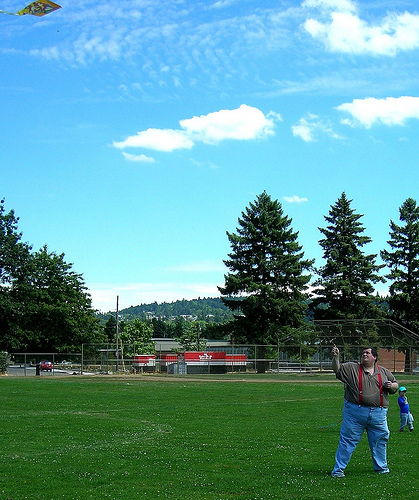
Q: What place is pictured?
A: It is a park.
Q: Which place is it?
A: It is a park.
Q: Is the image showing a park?
A: Yes, it is showing a park.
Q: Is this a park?
A: Yes, it is a park.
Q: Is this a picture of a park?
A: Yes, it is showing a park.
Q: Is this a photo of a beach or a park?
A: It is showing a park.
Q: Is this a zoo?
A: No, it is a park.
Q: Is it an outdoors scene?
A: Yes, it is outdoors.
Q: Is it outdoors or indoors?
A: It is outdoors.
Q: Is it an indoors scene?
A: No, it is outdoors.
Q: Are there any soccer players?
A: No, there are no soccer players.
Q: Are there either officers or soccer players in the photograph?
A: No, there are no soccer players or officers.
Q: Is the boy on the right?
A: Yes, the boy is on the right of the image.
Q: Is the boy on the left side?
A: No, the boy is on the right of the image.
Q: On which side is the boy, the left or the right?
A: The boy is on the right of the image.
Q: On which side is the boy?
A: The boy is on the right of the image.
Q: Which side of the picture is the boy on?
A: The boy is on the right of the image.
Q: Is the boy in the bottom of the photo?
A: Yes, the boy is in the bottom of the image.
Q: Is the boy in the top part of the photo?
A: No, the boy is in the bottom of the image.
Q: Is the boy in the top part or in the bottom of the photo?
A: The boy is in the bottom of the image.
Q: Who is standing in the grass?
A: The boy is standing in the grass.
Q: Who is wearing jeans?
A: The boy is wearing jeans.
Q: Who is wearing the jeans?
A: The boy is wearing jeans.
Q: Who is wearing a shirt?
A: The boy is wearing a shirt.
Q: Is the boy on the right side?
A: Yes, the boy is on the right of the image.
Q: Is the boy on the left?
A: No, the boy is on the right of the image.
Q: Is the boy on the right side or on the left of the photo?
A: The boy is on the right of the image.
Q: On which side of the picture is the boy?
A: The boy is on the right of the image.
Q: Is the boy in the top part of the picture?
A: No, the boy is in the bottom of the image.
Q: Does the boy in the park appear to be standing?
A: Yes, the boy is standing.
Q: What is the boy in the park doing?
A: The boy is standing.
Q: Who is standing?
A: The boy is standing.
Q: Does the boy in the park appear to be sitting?
A: No, the boy is standing.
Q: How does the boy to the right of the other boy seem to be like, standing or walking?
A: The boy is standing.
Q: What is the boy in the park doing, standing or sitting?
A: The boy is standing.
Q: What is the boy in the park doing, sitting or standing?
A: The boy is standing.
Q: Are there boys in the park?
A: Yes, there is a boy in the park.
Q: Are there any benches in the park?
A: No, there is a boy in the park.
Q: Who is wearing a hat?
A: The boy is wearing a hat.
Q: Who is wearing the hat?
A: The boy is wearing a hat.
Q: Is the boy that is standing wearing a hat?
A: Yes, the boy is wearing a hat.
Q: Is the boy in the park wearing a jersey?
A: No, the boy is wearing a hat.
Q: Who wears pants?
A: The boy wears pants.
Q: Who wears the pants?
A: The boy wears pants.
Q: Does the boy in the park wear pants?
A: Yes, the boy wears pants.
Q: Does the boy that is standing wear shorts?
A: No, the boy wears pants.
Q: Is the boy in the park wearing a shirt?
A: Yes, the boy is wearing a shirt.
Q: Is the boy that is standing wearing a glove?
A: No, the boy is wearing a shirt.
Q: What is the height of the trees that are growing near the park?
A: The trees are tall.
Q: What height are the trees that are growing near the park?
A: The trees are tall.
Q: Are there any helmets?
A: No, there are no helmets.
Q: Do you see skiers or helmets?
A: No, there are no helmets or skiers.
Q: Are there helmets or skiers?
A: No, there are no helmets or skiers.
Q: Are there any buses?
A: No, there are no buses.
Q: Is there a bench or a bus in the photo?
A: No, there are no buses or benches.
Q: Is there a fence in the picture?
A: Yes, there is a fence.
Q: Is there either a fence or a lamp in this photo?
A: Yes, there is a fence.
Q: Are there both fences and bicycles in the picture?
A: No, there is a fence but no bikes.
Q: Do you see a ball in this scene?
A: No, there are no balls.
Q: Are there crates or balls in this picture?
A: No, there are no balls or crates.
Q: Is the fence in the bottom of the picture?
A: Yes, the fence is in the bottom of the image.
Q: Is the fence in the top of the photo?
A: No, the fence is in the bottom of the image.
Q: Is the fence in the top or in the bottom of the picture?
A: The fence is in the bottom of the image.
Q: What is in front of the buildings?
A: The fence is in front of the buildings.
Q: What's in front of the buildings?
A: The fence is in front of the buildings.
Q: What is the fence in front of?
A: The fence is in front of the buildings.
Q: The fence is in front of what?
A: The fence is in front of the buildings.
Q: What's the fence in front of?
A: The fence is in front of the buildings.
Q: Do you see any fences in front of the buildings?
A: Yes, there is a fence in front of the buildings.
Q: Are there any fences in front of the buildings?
A: Yes, there is a fence in front of the buildings.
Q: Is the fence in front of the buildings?
A: Yes, the fence is in front of the buildings.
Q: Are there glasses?
A: No, there are no glasses.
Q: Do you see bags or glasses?
A: No, there are no glasses or bags.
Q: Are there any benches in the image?
A: No, there are no benches.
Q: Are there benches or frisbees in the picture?
A: No, there are no benches or frisbees.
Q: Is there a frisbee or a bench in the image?
A: No, there are no benches or frisbees.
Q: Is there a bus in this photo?
A: No, there are no buses.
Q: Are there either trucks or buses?
A: No, there are no buses or trucks.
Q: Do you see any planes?
A: No, there are no planes.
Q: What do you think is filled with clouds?
A: The sky is filled with clouds.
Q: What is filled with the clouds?
A: The sky is filled with clouds.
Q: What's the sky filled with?
A: The sky is filled with clouds.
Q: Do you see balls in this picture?
A: No, there are no balls.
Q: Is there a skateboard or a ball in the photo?
A: No, there are no balls or skateboards.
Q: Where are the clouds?
A: The clouds are in the sky.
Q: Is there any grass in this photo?
A: Yes, there is grass.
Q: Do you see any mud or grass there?
A: Yes, there is grass.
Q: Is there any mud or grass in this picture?
A: Yes, there is grass.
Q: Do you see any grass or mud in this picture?
A: Yes, there is grass.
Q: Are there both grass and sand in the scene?
A: No, there is grass but no sand.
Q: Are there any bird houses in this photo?
A: No, there are no bird houses.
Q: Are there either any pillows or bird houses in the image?
A: No, there are no bird houses or pillows.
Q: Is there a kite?
A: Yes, there is a kite.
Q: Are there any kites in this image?
A: Yes, there is a kite.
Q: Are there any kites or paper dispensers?
A: Yes, there is a kite.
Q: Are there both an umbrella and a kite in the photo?
A: No, there is a kite but no umbrellas.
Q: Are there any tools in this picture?
A: No, there are no tools.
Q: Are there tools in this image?
A: No, there are no tools.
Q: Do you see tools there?
A: No, there are no tools.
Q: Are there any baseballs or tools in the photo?
A: No, there are no tools or baseballs.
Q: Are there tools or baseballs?
A: No, there are no tools or baseballs.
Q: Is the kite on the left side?
A: Yes, the kite is on the left of the image.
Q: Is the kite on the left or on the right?
A: The kite is on the left of the image.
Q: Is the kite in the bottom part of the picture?
A: No, the kite is in the top of the image.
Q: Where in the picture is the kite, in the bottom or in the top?
A: The kite is in the top of the image.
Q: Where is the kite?
A: The kite is in the sky.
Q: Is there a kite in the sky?
A: Yes, there is a kite in the sky.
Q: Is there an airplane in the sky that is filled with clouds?
A: No, there is a kite in the sky.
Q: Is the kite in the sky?
A: Yes, the kite is in the sky.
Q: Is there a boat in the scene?
A: No, there are no boats.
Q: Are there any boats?
A: No, there are no boats.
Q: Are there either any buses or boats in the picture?
A: No, there are no boats or buses.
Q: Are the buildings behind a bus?
A: No, the buildings are behind the fence.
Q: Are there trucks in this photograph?
A: No, there are no trucks.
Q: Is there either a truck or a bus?
A: No, there are no trucks or buses.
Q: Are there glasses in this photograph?
A: No, there are no glasses.